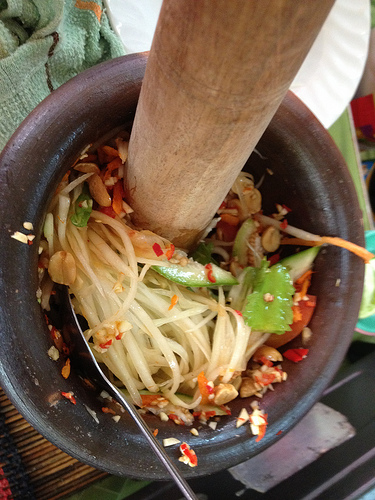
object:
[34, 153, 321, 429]
ingredients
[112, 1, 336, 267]
pestle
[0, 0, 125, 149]
towel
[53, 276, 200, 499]
fork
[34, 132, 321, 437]
food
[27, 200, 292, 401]
sprouts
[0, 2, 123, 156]
cloth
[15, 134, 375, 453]
mixed food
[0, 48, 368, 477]
cup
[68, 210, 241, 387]
noodles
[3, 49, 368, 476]
bowl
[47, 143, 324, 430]
vegetable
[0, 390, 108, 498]
bamboo placemat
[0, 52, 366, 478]
mortar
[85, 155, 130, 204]
pepper seed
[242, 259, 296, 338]
leaf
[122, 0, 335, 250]
post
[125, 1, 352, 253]
pestle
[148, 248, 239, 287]
lettuce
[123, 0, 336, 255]
stick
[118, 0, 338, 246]
mortar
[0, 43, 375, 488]
pestle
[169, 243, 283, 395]
spices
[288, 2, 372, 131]
plate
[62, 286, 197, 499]
utensil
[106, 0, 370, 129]
paper plate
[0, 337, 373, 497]
table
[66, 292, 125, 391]
edge